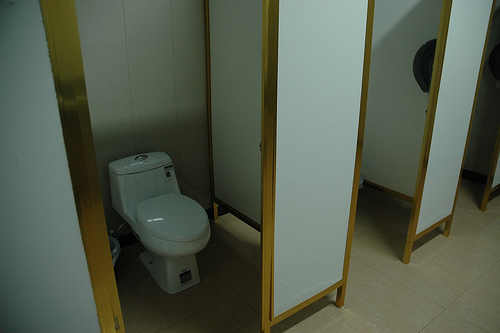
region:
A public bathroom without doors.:
[0, 0, 498, 331]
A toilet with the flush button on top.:
[105, 146, 211, 296]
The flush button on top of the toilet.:
[132, 151, 149, 164]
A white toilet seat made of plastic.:
[131, 188, 209, 243]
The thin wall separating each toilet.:
[200, 0, 375, 330]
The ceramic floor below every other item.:
[122, 195, 494, 330]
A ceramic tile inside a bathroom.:
[345, 200, 495, 307]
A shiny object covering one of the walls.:
[35, 0, 126, 332]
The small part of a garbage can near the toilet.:
[107, 233, 120, 266]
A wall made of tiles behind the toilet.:
[77, 2, 204, 243]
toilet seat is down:
[130, 188, 210, 249]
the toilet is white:
[96, 130, 241, 320]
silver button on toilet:
[120, 140, 157, 175]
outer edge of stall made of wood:
[35, 0, 146, 325]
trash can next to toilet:
[100, 215, 140, 290]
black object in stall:
[392, 25, 452, 95]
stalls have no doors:
[57, 1, 484, 256]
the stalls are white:
[0, 4, 499, 274]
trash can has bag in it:
[103, 229, 133, 286]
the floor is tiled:
[106, 202, 493, 322]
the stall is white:
[0, 0, 497, 331]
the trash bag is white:
[107, 233, 127, 273]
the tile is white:
[68, 3, 216, 241]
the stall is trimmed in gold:
[38, 0, 499, 332]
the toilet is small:
[98, 142, 220, 302]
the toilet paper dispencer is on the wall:
[406, 27, 447, 108]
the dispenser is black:
[412, 29, 447, 105]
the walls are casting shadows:
[68, 92, 499, 327]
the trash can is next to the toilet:
[106, 228, 123, 280]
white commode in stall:
[113, 122, 231, 314]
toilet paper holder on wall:
[406, 38, 433, 100]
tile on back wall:
[126, 47, 175, 138]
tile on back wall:
[127, 0, 174, 42]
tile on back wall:
[78, 38, 131, 145]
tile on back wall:
[169, 43, 205, 135]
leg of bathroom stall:
[390, 242, 418, 267]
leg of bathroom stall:
[327, 289, 352, 315]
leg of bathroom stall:
[437, 219, 456, 239]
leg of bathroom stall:
[476, 199, 488, 213]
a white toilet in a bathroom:
[99, 133, 221, 303]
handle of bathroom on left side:
[160, 157, 178, 180]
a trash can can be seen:
[100, 215, 129, 275]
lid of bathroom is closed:
[126, 182, 224, 262]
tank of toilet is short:
[102, 141, 189, 222]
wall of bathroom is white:
[82, 5, 258, 155]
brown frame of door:
[33, 0, 278, 330]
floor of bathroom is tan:
[352, 232, 495, 330]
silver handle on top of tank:
[128, 144, 155, 166]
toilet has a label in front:
[171, 263, 198, 288]